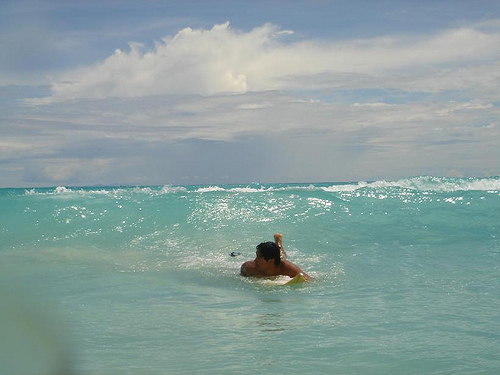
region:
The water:
[218, 308, 418, 372]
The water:
[330, 272, 392, 368]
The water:
[362, 289, 415, 368]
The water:
[324, 328, 364, 365]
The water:
[384, 315, 445, 372]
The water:
[333, 323, 435, 373]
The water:
[337, 289, 392, 342]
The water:
[313, 313, 370, 349]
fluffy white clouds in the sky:
[51, 10, 422, 155]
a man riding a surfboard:
[201, 233, 323, 320]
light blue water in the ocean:
[2, 220, 181, 370]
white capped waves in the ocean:
[304, 168, 490, 218]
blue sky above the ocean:
[31, 7, 121, 45]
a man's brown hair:
[243, 236, 285, 269]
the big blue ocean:
[3, 181, 498, 373]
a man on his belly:
[194, 211, 328, 306]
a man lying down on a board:
[214, 216, 309, 306]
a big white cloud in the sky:
[58, 14, 349, 140]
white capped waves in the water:
[282, 141, 482, 229]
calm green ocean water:
[16, 282, 176, 354]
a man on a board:
[218, 210, 306, 318]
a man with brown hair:
[244, 231, 287, 268]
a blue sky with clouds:
[263, 11, 446, 58]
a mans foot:
[270, 224, 287, 251]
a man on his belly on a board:
[206, 223, 320, 305]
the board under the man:
[266, 262, 316, 288]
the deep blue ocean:
[7, 167, 492, 220]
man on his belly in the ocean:
[210, 217, 315, 311]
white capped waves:
[140, 166, 459, 211]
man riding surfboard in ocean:
[209, 224, 317, 316]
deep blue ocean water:
[3, 172, 487, 199]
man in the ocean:
[210, 217, 325, 295]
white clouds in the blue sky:
[53, 29, 340, 137]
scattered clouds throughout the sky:
[275, 42, 454, 165]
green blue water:
[25, 254, 206, 366]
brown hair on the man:
[250, 240, 288, 270]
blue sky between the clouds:
[8, 5, 127, 73]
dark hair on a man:
[254, 237, 284, 260]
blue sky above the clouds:
[2, 1, 498, 51]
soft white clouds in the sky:
[10, 31, 492, 187]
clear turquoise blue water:
[4, 178, 495, 369]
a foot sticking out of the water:
[273, 230, 286, 242]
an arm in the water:
[283, 264, 312, 289]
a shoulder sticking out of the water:
[238, 257, 255, 278]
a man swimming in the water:
[240, 229, 310, 289]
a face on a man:
[254, 251, 268, 267]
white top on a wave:
[321, 182, 368, 192]